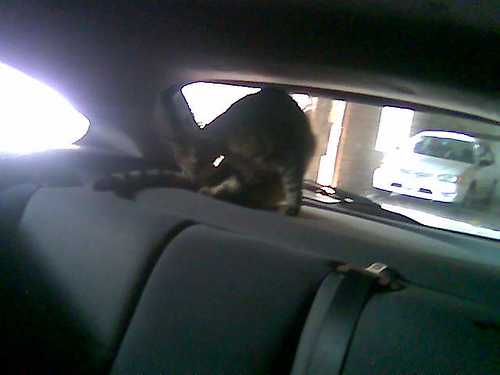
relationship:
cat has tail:
[95, 92, 312, 215] [84, 157, 191, 195]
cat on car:
[95, 92, 312, 215] [4, 3, 498, 372]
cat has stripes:
[95, 92, 312, 215] [281, 156, 299, 215]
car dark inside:
[4, 3, 498, 372] [4, 6, 490, 369]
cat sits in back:
[95, 92, 312, 215] [148, 77, 497, 241]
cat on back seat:
[95, 92, 312, 215] [140, 151, 498, 274]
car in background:
[371, 129, 493, 206] [343, 101, 494, 234]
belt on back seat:
[307, 261, 381, 373] [8, 199, 485, 371]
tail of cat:
[94, 168, 198, 188] [95, 92, 312, 215]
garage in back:
[334, 111, 500, 226] [339, 99, 500, 228]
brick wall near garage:
[337, 102, 383, 196] [334, 111, 500, 226]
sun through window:
[4, 66, 90, 149] [1, 68, 91, 151]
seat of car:
[8, 199, 485, 371] [4, 3, 498, 372]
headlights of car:
[438, 175, 461, 185] [371, 129, 493, 206]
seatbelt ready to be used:
[307, 261, 381, 373] [308, 264, 392, 375]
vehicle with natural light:
[4, 3, 498, 372] [6, 69, 306, 152]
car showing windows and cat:
[4, 3, 498, 372] [95, 92, 312, 215]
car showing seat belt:
[4, 3, 498, 372] [307, 261, 381, 373]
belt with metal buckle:
[307, 261, 381, 373] [364, 260, 386, 276]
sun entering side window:
[4, 66, 90, 149] [1, 68, 91, 151]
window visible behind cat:
[181, 80, 500, 230] [95, 92, 312, 215]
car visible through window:
[371, 129, 493, 206] [181, 80, 500, 230]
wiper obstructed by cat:
[304, 176, 395, 215] [95, 92, 312, 215]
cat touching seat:
[95, 92, 312, 215] [8, 199, 485, 371]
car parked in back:
[371, 129, 493, 206] [148, 77, 497, 241]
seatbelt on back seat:
[307, 261, 381, 373] [8, 199, 485, 371]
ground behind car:
[366, 190, 499, 229] [4, 3, 498, 372]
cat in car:
[95, 92, 312, 215] [4, 3, 498, 372]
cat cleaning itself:
[95, 92, 312, 215] [91, 86, 316, 213]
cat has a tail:
[95, 92, 312, 215] [94, 168, 198, 188]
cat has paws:
[95, 92, 312, 215] [198, 184, 298, 216]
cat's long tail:
[95, 92, 312, 215] [94, 168, 198, 188]